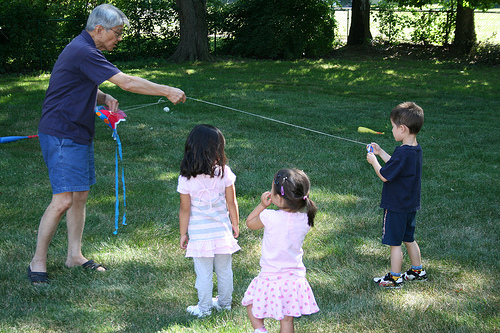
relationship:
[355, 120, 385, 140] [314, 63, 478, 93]
toy bat in grass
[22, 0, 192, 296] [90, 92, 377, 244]
adult flying kite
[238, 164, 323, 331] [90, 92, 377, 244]
girl flying kite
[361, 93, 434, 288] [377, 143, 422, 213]
boy wearing blue shirt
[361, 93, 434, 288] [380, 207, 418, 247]
boy wearing blue shorts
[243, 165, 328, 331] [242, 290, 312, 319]
girl wearing shirt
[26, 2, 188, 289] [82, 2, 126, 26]
adult has hair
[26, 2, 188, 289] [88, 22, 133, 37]
adult wearing glasses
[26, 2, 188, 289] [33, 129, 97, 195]
adult wearing blue shorts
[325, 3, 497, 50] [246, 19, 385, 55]
fence behind trees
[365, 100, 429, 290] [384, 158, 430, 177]
boy wearing blue shirt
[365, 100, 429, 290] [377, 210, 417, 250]
boy wearing blue shorts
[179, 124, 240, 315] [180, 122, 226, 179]
girl with hair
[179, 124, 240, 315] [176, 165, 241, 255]
girl wearing shirt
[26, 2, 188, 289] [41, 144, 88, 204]
adult wearing blue shorts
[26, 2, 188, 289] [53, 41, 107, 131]
adult wearing blue shirt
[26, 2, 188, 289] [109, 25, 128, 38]
adult wearing glasses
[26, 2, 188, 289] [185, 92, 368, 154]
adult holding string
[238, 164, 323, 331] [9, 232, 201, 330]
girl standing on grass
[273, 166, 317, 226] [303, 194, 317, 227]
hair pulled into ponytail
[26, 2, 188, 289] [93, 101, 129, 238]
adult holding kite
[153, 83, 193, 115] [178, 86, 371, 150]
hand on string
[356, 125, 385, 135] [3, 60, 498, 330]
toy bat laying on grass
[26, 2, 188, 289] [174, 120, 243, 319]
adult playing with girl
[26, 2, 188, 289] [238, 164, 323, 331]
adult playing with girl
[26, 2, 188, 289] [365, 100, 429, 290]
adult playing with boy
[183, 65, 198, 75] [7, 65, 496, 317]
light shining on ground